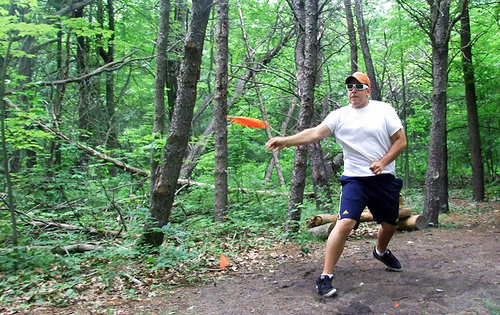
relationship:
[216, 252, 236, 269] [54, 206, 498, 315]
flag on ground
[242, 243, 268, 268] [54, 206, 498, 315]
leaves on ground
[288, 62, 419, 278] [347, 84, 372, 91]
man wearing sunglasses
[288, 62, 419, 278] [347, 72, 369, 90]
man wearing hat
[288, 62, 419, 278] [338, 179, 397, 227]
man wearing shorts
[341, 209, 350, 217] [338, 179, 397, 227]
logo on shorts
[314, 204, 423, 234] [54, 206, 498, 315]
logs on ground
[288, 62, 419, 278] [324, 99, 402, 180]
man wearing shirt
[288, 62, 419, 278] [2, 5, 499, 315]
man in forest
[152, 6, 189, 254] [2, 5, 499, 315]
tree in forest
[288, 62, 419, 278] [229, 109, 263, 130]
man throwing frisbee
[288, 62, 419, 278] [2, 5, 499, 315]
man standing in forest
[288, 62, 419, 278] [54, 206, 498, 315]
man standing on ground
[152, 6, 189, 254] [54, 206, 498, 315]
tree in ground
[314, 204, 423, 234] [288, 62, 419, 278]
logs behind man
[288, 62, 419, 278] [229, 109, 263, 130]
man playing frisbee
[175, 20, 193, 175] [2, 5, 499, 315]
trunk in forest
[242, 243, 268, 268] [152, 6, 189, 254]
leaves on tree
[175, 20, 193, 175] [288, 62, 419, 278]
trunk behind man